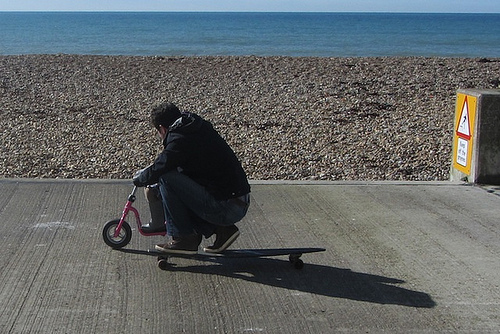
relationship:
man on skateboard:
[133, 103, 252, 254] [144, 247, 325, 266]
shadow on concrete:
[176, 252, 431, 309] [1, 178, 499, 333]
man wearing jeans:
[133, 103, 252, 254] [160, 172, 249, 238]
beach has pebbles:
[0, 54, 498, 183] [0, 55, 499, 182]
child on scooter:
[142, 182, 163, 235] [103, 180, 167, 248]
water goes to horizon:
[2, 12, 498, 58] [1, 8, 498, 18]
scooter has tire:
[103, 180, 167, 248] [103, 219, 132, 251]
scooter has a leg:
[103, 180, 167, 248] [138, 183, 166, 230]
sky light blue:
[1, 2, 499, 14] [0, 1, 498, 58]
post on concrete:
[449, 90, 499, 182] [1, 178, 499, 332]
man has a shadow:
[133, 103, 252, 254] [176, 252, 431, 309]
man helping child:
[133, 103, 252, 254] [142, 182, 163, 235]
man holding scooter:
[133, 103, 252, 254] [103, 180, 167, 248]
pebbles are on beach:
[0, 55, 499, 182] [0, 54, 498, 183]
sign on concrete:
[449, 92, 476, 175] [1, 178, 499, 332]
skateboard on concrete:
[144, 247, 325, 266] [1, 178, 499, 333]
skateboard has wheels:
[144, 247, 325, 266] [158, 259, 307, 271]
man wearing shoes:
[133, 103, 252, 254] [156, 226, 237, 253]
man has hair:
[133, 103, 252, 254] [150, 102, 179, 127]